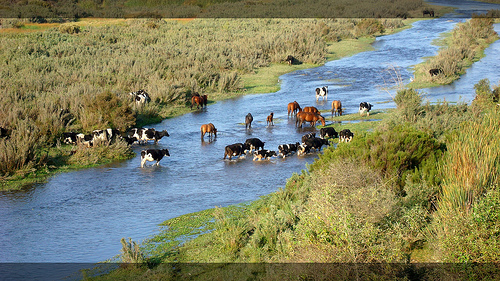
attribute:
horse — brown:
[289, 106, 336, 128]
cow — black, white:
[303, 82, 333, 101]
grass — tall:
[233, 136, 481, 266]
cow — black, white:
[127, 143, 175, 173]